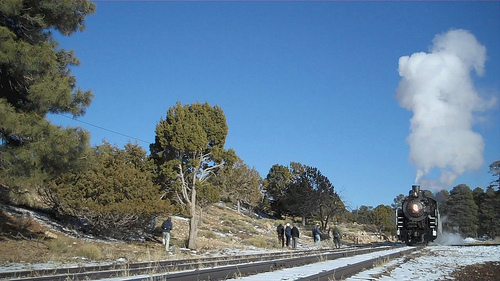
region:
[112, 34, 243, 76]
Clear blue sky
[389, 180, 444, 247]
Moving train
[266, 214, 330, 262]
People walking near train tracks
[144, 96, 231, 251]
Man next to tree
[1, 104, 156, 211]
Green leaves on trees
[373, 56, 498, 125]
white smoke emanating from train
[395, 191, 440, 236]
large white spot on front of train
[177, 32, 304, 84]
clear blue skies overhead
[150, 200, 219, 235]
large brown cement block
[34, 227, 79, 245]
large stone on ground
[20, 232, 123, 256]
messy green grass on ground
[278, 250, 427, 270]
large patch of snow between train tracks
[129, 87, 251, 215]
large green trees with leaves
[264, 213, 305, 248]
men walking on the grass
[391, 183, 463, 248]
large black train coming down the tracks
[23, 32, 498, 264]
There are people walking near the tracks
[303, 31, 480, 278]
Smoke is coming from the train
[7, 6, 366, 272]
There are trees in the background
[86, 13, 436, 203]
The sky is blue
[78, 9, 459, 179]
There are no clouds in the sky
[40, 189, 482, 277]
There is snow on the ground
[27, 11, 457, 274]
The photo was taken in the daytime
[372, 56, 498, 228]
The smoke is white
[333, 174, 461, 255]
The front of the train is black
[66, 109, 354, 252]
There is a small hill next to the people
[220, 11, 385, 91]
Clear blue sky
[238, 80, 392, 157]
Clear blue sky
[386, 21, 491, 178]
White smoke from train against blue sky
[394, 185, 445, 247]
Black train moving on tracks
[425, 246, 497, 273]
White and brown ground near train tracks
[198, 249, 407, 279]
Brown train tracks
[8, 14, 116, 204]
Green leaves on brown trees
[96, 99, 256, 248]
Green leaves on brown trees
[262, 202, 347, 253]
People waiting near train tracks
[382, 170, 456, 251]
A black train on the tracks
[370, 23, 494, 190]
The steam is coming from the train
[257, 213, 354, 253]
People stand and watch the train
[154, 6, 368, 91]
The sky is blue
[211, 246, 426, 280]
Train tracks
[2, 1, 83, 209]
Green Trees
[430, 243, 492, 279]
Gravel on the ground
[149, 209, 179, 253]
A person off to himself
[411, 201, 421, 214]
A headlight on the train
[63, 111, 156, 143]
A black power line